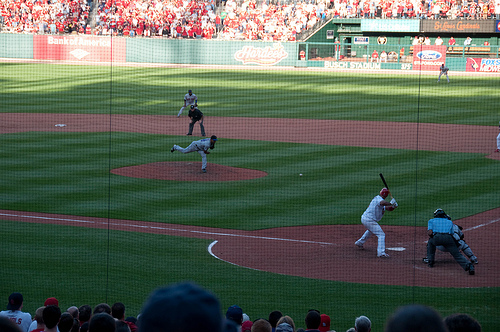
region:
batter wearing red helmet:
[353, 172, 398, 260]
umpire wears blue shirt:
[425, 209, 473, 275]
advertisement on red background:
[412, 45, 446, 71]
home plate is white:
[386, 240, 406, 255]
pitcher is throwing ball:
[165, 133, 222, 170]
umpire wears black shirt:
[181, 104, 210, 135]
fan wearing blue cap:
[1, 291, 35, 326]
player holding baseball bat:
[353, 170, 398, 260]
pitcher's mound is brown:
[113, 158, 267, 183]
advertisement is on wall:
[31, 35, 127, 61]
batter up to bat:
[357, 171, 398, 267]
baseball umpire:
[418, 200, 490, 277]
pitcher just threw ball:
[165, 132, 230, 179]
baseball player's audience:
[0, 273, 305, 330]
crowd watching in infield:
[106, 0, 278, 47]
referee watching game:
[180, 100, 213, 137]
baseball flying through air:
[280, 160, 315, 181]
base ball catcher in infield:
[430, 62, 477, 88]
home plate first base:
[356, 219, 491, 301]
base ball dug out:
[322, 25, 451, 73]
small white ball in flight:
[285, 159, 315, 182]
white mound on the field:
[57, 112, 69, 132]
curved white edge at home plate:
[193, 226, 237, 283]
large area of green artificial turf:
[224, 65, 364, 112]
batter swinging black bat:
[367, 157, 409, 215]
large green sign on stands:
[358, 13, 423, 38]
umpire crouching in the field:
[175, 102, 222, 134]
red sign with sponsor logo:
[29, 24, 121, 71]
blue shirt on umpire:
[403, 210, 476, 239]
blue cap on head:
[98, 264, 245, 318]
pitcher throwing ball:
[168, 134, 305, 176]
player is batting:
[354, 172, 401, 257]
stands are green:
[0, 17, 499, 77]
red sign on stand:
[32, 32, 126, 62]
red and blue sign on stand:
[412, 44, 446, 70]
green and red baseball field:
[1, 61, 498, 330]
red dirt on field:
[0, 113, 498, 158]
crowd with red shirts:
[1, 0, 498, 42]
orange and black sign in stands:
[420, 20, 495, 32]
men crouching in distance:
[180, 87, 205, 134]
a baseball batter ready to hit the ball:
[346, 174, 416, 258]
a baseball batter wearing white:
[353, 188, 390, 268]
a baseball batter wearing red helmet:
[376, 175, 393, 201]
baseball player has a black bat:
[374, 164, 391, 196]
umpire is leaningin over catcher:
[423, 203, 477, 275]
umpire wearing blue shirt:
[419, 205, 487, 280]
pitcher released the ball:
[170, 136, 223, 171]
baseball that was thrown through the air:
[293, 164, 306, 181]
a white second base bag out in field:
[51, 112, 67, 132]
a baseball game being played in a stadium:
[8, 52, 473, 274]